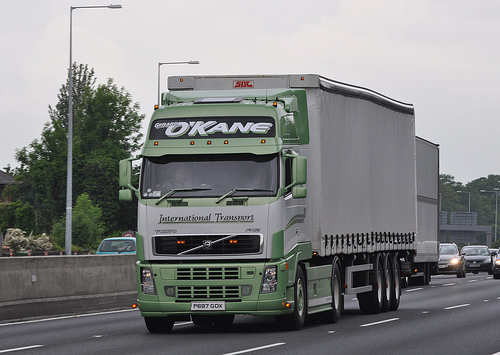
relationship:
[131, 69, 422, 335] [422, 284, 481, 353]
truck on road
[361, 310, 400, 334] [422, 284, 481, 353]
line on road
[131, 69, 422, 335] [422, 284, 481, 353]
truck in road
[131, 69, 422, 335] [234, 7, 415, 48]
truck below sky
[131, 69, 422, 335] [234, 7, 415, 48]
truck near sky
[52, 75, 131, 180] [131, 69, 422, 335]
tree near truck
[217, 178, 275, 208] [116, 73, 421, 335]
wiper on truck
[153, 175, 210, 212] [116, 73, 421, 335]
wiper on truck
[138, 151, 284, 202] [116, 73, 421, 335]
windshield on truck